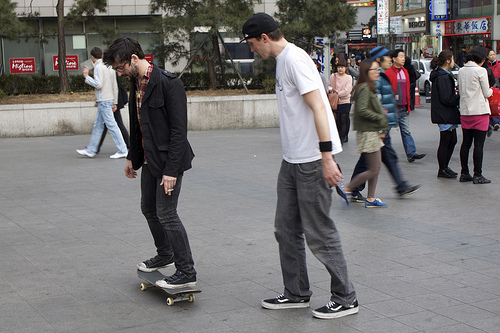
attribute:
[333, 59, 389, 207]
pedestrian — walking around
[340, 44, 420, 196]
pedestrian — walking around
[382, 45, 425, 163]
pedestrian — walking around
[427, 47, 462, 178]
pedestrian — walking around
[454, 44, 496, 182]
pedestrian — walking around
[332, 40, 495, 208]
group — walking around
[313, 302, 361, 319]
sneaker — nike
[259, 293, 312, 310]
sneaker — nike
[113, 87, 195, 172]
jacket — black 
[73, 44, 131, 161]
person — walking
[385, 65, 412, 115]
coat — red 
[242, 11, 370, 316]
man — black 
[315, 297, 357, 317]
shoe — white 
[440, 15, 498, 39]
sign — red 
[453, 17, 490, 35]
writing — white 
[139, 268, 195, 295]
grip tape — black 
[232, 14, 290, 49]
hat — Black 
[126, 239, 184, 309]
skateboard — black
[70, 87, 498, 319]
walkway — square patterned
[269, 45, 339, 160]
shirt — white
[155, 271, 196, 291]
shoe — Black , white 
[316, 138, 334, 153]
wristband — Black 